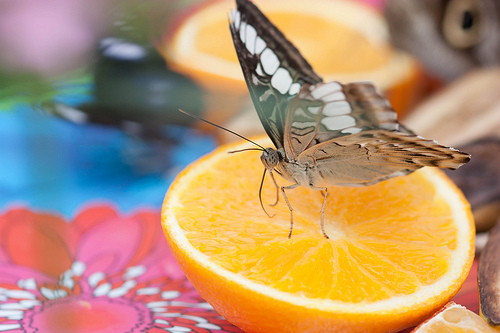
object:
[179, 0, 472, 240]
butterfly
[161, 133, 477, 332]
orange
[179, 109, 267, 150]
antennae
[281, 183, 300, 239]
leg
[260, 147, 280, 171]
head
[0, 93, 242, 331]
table cloth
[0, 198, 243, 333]
flower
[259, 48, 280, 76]
spot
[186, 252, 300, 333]
peel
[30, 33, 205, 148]
butterfly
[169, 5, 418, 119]
orange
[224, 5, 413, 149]
wing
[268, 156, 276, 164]
eye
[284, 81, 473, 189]
wing